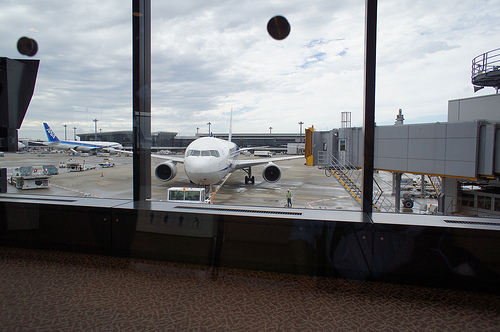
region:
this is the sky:
[185, 5, 231, 68]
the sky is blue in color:
[180, 5, 231, 32]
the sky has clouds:
[178, 0, 257, 101]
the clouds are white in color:
[184, 19, 239, 81]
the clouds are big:
[187, 25, 227, 82]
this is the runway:
[90, 167, 117, 188]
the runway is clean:
[92, 170, 125, 189]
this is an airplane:
[43, 116, 311, 196]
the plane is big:
[181, 131, 241, 177]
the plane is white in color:
[198, 158, 208, 167]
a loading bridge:
[294, 119, 489, 210]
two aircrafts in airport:
[21, 118, 311, 200]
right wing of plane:
[230, 145, 302, 162]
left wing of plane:
[100, 145, 180, 161]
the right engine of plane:
[260, 160, 285, 186]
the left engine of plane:
[152, 157, 180, 182]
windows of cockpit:
[181, 138, 221, 164]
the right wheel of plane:
[241, 170, 259, 185]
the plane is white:
[103, 130, 310, 195]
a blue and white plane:
[25, 116, 130, 160]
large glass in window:
[168, 14, 352, 181]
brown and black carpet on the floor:
[31, 260, 238, 319]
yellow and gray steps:
[324, 153, 381, 205]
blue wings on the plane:
[35, 116, 70, 146]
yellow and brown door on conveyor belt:
[292, 125, 322, 167]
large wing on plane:
[251, 158, 293, 187]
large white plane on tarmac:
[100, 117, 310, 183]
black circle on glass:
[250, 12, 300, 43]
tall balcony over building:
[461, 40, 492, 93]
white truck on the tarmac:
[97, 153, 124, 178]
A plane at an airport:
[161, 99, 313, 213]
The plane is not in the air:
[112, 122, 302, 197]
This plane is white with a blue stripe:
[30, 106, 115, 153]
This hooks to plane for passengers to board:
[304, 104, 484, 185]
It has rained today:
[258, 168, 329, 203]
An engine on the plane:
[260, 157, 290, 182]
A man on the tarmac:
[276, 188, 297, 216]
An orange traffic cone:
[98, 166, 113, 178]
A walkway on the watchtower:
[456, 35, 496, 83]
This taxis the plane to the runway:
[158, 176, 228, 211]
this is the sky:
[181, 9, 258, 97]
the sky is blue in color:
[51, 72, 111, 112]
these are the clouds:
[202, 32, 253, 63]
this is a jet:
[183, 109, 251, 181]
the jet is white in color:
[193, 159, 226, 180]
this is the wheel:
[238, 165, 262, 190]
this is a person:
[282, 175, 302, 212]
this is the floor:
[88, 275, 197, 316]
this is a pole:
[89, 110, 101, 138]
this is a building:
[95, 128, 119, 142]